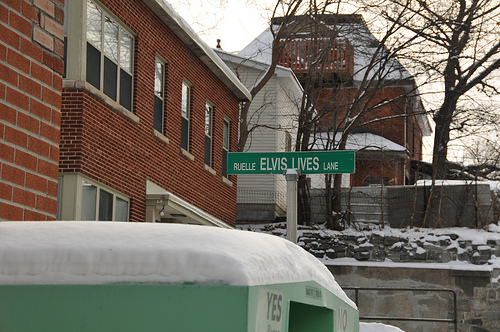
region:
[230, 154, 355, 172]
green street sign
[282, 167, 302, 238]
a pole holding a green sign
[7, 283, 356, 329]
a green structure in front of the sign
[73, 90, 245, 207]
a red brick building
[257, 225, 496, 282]
a rock slab birm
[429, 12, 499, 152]
a tree in the backdrop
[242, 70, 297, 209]
a white house in the backdrop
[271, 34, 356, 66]
balcony on the house in the backdrop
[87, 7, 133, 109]
window on the brick building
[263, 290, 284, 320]
black lettering on the green structure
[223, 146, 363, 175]
Elvis lives sign on street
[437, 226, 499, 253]
snow on the ground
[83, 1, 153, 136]
windows in the building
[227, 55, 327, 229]
building with vinyl siding on it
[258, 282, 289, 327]
sign that says yes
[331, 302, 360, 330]
sign that says no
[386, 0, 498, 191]
a tree with no leaves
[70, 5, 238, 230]
a brick building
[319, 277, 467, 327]
a metal railing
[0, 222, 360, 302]
a snow covered vehicle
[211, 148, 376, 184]
Elvis street sign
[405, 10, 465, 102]
Barren trees over winter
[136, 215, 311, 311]
Snow on roof of green vehicle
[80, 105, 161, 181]
red brick building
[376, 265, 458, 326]
black iron railing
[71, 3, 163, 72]
window reflecting tree branches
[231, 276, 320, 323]
printed yes word on vehicle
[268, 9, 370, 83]
balcony on top floor of building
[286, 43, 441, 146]
tree branches leaning towards light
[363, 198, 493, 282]
stone wall covered in snow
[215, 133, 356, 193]
green street sign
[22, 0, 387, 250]
large red apartment building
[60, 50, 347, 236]
red brick apartment building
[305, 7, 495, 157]
a bare snow covered trees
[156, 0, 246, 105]
snow covered roof top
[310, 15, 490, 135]
trees with snow on the branches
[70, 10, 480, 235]
three tall buildings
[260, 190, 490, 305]
snow covered gray rocks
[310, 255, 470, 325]
snow covered metal railing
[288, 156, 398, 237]
snow covered stairs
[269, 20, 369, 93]
a wood balcony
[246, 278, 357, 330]
the words yes and no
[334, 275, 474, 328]
a metal railing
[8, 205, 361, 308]
a blanket of snow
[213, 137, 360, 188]
a street sign that says elvis lives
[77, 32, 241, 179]
a row of windows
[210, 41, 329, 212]
a white building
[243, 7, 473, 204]
trees that have no leaves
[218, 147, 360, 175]
a green rectangle sign